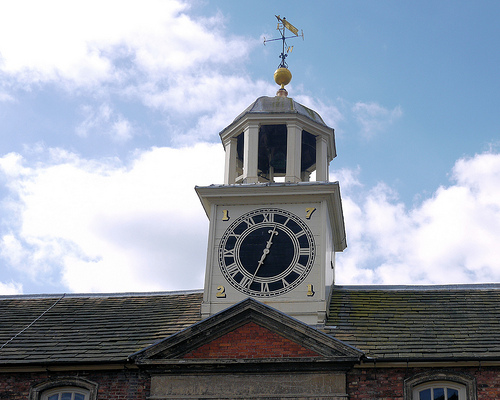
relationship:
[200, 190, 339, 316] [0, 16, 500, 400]
clock on bank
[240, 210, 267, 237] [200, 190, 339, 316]
number on clock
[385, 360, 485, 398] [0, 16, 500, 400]
window on bank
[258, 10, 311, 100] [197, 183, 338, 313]
compass on clock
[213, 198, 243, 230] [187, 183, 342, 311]
number around clock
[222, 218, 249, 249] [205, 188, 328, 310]
numeral on clock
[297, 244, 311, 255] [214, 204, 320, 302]
roman numeral on clock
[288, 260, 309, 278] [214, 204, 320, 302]
roman numeral on clock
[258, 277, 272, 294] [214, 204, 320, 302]
roman numeral on clock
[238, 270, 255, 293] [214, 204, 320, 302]
roman numeral on clock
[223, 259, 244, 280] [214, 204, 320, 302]
roman numeral on clock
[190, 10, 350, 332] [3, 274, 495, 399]
clock tower on building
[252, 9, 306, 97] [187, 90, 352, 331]
weather vane on clock tower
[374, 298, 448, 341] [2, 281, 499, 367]
section of a roof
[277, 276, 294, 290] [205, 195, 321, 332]
roman numeral on a clock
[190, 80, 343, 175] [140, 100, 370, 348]
open cupola on top of clock tower